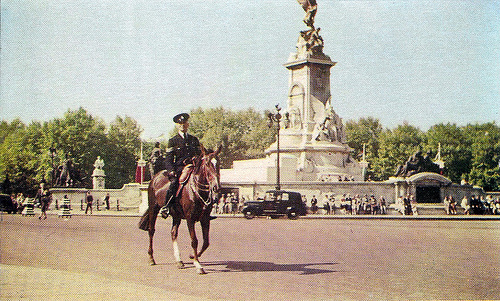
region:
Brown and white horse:
[156, 173, 211, 257]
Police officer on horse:
[160, 110, 233, 245]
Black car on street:
[248, 187, 318, 222]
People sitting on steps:
[312, 195, 392, 216]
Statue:
[282, 21, 355, 203]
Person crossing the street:
[31, 180, 48, 225]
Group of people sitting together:
[460, 190, 495, 220]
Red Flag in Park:
[127, 153, 148, 183]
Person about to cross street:
[77, 186, 94, 217]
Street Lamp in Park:
[43, 137, 62, 196]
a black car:
[240, 190, 310, 221]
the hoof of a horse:
[193, 265, 208, 277]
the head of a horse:
[194, 138, 227, 198]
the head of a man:
[170, 112, 193, 133]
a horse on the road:
[134, 140, 231, 275]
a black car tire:
[286, 208, 301, 220]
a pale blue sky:
[1, 0, 499, 142]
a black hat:
[171, 110, 188, 123]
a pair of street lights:
[265, 104, 292, 133]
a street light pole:
[273, 129, 285, 189]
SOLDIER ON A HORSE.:
[131, 107, 233, 271]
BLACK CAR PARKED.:
[234, 181, 313, 236]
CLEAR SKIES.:
[78, 20, 228, 82]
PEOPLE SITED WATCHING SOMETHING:
[311, 192, 497, 223]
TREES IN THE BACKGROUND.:
[0, 116, 102, 191]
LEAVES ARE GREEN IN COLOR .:
[442, 127, 492, 182]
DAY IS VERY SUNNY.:
[2, 23, 493, 295]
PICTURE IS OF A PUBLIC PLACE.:
[5, 91, 491, 297]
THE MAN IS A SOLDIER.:
[164, 105, 196, 231]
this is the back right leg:
[145, 191, 160, 275]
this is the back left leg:
[160, 200, 190, 277]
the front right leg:
[180, 212, 214, 279]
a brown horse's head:
[177, 122, 234, 197]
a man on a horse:
[122, 90, 234, 285]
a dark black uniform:
[151, 136, 211, 217]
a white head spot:
[201, 149, 225, 174]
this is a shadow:
[151, 235, 341, 295]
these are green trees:
[19, 107, 124, 200]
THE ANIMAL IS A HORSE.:
[140, 148, 231, 262]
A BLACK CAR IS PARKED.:
[236, 180, 311, 226]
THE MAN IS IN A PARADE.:
[141, 110, 245, 266]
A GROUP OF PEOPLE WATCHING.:
[316, 190, 493, 217]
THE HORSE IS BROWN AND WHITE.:
[151, 152, 231, 281]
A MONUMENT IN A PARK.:
[265, 2, 355, 178]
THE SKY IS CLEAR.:
[53, 10, 243, 88]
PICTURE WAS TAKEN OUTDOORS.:
[6, 4, 489, 299]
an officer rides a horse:
[157, 109, 210, 220]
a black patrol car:
[239, 185, 310, 222]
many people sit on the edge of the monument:
[308, 192, 498, 224]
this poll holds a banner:
[132, 137, 149, 186]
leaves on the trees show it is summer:
[1, 101, 498, 194]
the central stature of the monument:
[284, 5, 334, 52]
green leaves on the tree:
[465, 139, 482, 154]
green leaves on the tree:
[221, 112, 249, 150]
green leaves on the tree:
[367, 145, 422, 199]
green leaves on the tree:
[52, 123, 109, 181]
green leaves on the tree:
[64, 100, 96, 128]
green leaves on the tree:
[11, 145, 42, 172]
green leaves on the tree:
[7, 130, 107, 185]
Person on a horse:
[126, 102, 229, 281]